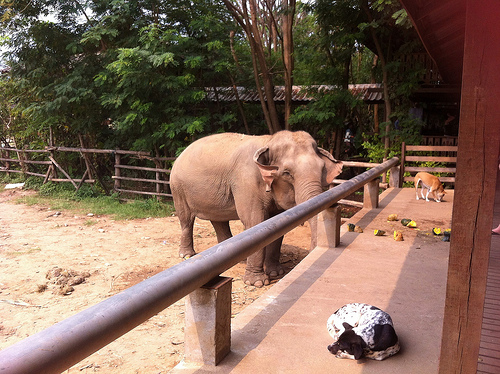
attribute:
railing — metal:
[1, 149, 413, 369]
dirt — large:
[1, 180, 311, 370]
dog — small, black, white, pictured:
[322, 300, 404, 365]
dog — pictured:
[327, 300, 403, 362]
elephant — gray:
[147, 123, 372, 248]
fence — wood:
[6, 115, 232, 232]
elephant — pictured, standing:
[164, 126, 343, 290]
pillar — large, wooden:
[435, 0, 499, 372]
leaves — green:
[82, 41, 199, 145]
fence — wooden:
[4, 142, 394, 216]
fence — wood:
[0, 143, 172, 195]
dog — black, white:
[314, 291, 406, 372]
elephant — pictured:
[161, 117, 353, 295]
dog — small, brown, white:
[411, 166, 449, 213]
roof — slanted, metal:
[198, 75, 384, 107]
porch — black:
[326, 230, 458, 325]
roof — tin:
[204, 84, 385, 103]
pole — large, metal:
[1, 157, 400, 371]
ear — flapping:
[252, 142, 280, 194]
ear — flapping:
[316, 145, 344, 187]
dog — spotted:
[295, 294, 444, 366]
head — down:
[432, 189, 449, 203]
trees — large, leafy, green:
[22, 3, 222, 161]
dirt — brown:
[2, 186, 359, 372]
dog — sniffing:
[285, 265, 395, 347]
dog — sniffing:
[381, 163, 459, 227]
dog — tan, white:
[408, 166, 445, 204]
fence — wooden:
[3, 127, 387, 229]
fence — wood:
[7, 132, 392, 215]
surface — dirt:
[4, 182, 333, 369]